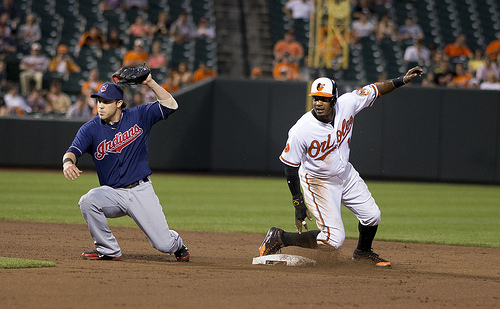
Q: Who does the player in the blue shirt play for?
A: Indians.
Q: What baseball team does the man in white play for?
A: Orioles.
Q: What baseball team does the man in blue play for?
A: Indians.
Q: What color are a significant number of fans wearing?
A: Orange.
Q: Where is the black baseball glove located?
A: Left hand of indians player.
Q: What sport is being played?
A: Major League baseball.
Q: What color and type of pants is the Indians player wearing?
A: Gray baseball pants.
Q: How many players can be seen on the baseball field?
A: 2.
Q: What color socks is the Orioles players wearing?
A: Black.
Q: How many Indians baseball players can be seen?
A: 1.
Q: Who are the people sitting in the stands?
A: Baseball fans.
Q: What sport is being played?
A: Baseball.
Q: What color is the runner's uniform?
A: White.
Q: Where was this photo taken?
A: Baseball stadium.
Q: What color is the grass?
A: Green.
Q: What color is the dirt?
A: Brown.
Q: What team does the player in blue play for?
A: Indians.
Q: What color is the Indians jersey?
A: Blue.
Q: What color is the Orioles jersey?
A: White.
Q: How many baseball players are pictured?
A: Two.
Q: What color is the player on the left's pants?
A: Grey.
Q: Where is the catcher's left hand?
A: In the air.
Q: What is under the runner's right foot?
A: A base.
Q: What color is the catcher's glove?
A: Black.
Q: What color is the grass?
A: Green.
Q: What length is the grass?
A: Short.